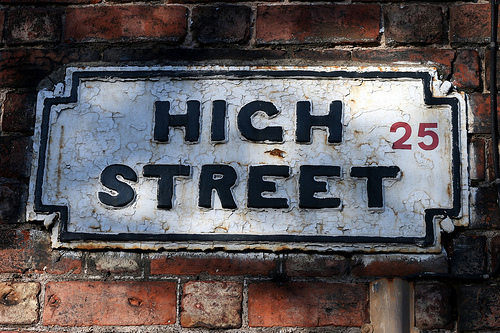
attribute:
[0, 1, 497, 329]
bricks — old, mismatched, stacked, red, holed, chipped, caulked, cracked, walled, rustic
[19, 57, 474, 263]
placque — white, trimmed, metal, old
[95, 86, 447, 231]
writing — black, red, blue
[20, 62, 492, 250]
sign — trimmed, white, black, cracked, rusty, chipped, old